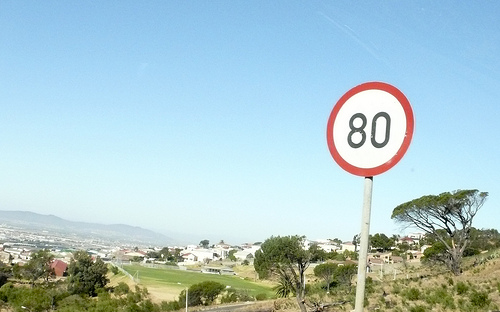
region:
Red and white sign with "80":
[309, 75, 436, 179]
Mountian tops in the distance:
[17, 174, 180, 231]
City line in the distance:
[17, 225, 238, 275]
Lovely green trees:
[393, 195, 495, 266]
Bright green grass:
[147, 264, 192, 292]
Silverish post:
[356, 176, 373, 310]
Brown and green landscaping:
[437, 260, 497, 310]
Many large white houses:
[188, 242, 260, 272]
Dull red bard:
[47, 252, 68, 278]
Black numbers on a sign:
[350, 101, 388, 155]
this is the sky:
[86, 25, 236, 147]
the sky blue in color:
[78, 30, 260, 211]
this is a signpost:
[321, 82, 405, 182]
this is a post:
[358, 182, 369, 309]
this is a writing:
[343, 107, 396, 149]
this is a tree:
[406, 183, 467, 271]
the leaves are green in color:
[407, 195, 437, 212]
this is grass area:
[148, 267, 181, 284]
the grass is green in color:
[148, 266, 165, 276]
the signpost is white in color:
[354, 149, 371, 162]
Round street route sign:
[302, 75, 433, 185]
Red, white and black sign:
[290, 65, 431, 195]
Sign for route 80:
[320, 77, 432, 182]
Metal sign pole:
[342, 172, 387, 307]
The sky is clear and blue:
[12, 16, 485, 230]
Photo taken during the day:
[15, 4, 498, 306]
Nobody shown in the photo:
[15, 10, 494, 304]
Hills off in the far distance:
[0, 200, 196, 251]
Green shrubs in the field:
[302, 281, 497, 309]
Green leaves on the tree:
[230, 237, 312, 267]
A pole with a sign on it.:
[327, 175, 382, 306]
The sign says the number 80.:
[320, 75, 415, 190]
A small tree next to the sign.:
[255, 227, 327, 307]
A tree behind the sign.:
[387, 186, 497, 277]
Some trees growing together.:
[11, 230, 117, 308]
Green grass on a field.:
[138, 265, 229, 280]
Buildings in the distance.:
[165, 236, 253, 271]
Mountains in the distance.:
[7, 205, 178, 245]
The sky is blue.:
[30, 31, 370, 74]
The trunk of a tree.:
[281, 260, 321, 310]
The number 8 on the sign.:
[337, 102, 372, 154]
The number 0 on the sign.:
[374, 105, 389, 152]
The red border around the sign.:
[319, 83, 421, 184]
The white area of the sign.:
[337, 95, 401, 158]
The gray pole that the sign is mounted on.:
[357, 170, 379, 306]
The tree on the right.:
[385, 182, 499, 298]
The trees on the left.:
[7, 236, 110, 311]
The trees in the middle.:
[176, 230, 371, 311]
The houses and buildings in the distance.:
[12, 213, 386, 290]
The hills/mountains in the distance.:
[1, 205, 192, 243]